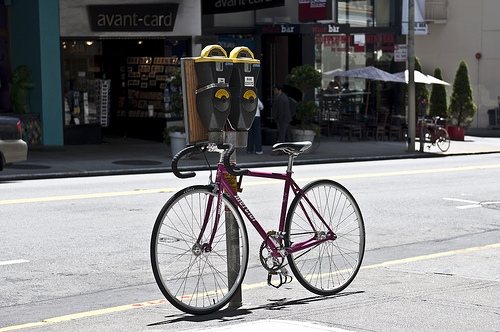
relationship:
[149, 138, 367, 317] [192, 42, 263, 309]
bike near parking meter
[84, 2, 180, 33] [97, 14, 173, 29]
sign has lettering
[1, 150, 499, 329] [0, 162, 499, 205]
street has line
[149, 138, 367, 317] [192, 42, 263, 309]
bike tied to parking meter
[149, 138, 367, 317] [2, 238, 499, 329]
bike on sidewalk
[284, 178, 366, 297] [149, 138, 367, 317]
tire of bike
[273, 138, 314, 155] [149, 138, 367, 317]
seat of bike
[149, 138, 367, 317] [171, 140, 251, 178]
bike has handle bars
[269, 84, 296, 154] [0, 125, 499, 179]
person standing on sidewalk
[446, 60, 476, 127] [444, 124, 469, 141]
tree in planter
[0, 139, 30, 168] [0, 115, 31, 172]
bumper of vehicle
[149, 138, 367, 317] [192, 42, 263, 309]
bike parked near parking meter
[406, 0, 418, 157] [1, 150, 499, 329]
pole on side of street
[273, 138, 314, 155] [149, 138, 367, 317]
seat on bike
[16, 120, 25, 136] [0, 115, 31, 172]
tail light of vehicle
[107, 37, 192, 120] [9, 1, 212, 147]
window on building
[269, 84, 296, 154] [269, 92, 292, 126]
person wearing suit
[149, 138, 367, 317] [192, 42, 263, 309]
bike leaning against parking meter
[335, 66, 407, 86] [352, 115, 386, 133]
umbrella over table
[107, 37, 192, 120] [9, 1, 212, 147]
window of building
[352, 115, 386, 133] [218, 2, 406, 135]
table outside of bar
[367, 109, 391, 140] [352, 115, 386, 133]
chair around table